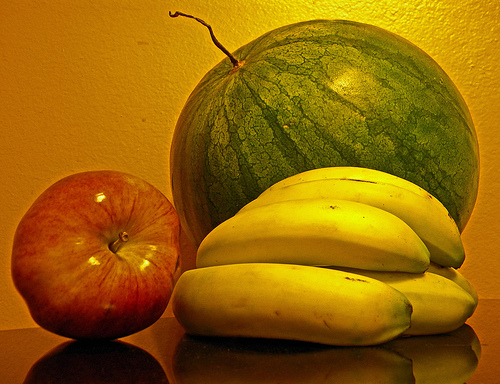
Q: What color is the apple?
A: Red.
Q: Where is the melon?
A: Behind the bananas.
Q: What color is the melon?
A: Green.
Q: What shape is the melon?
A: Round.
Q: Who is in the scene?
A: No one.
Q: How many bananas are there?
A: Five.